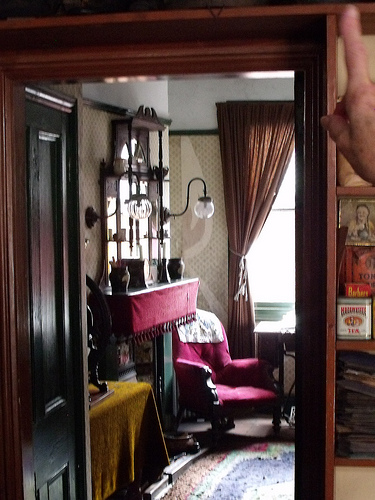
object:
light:
[161, 436, 291, 500]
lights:
[112, 149, 215, 220]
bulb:
[194, 202, 215, 220]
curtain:
[213, 99, 296, 358]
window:
[247, 115, 295, 321]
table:
[99, 277, 200, 414]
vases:
[108, 266, 130, 293]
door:
[0, 77, 87, 500]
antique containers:
[84, 102, 215, 292]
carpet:
[157, 438, 296, 500]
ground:
[130, 415, 296, 500]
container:
[336, 296, 371, 342]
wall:
[81, 76, 294, 135]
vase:
[167, 257, 185, 280]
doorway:
[1, 0, 339, 500]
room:
[0, 0, 375, 499]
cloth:
[103, 277, 201, 349]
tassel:
[192, 313, 198, 322]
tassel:
[184, 315, 187, 324]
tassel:
[167, 320, 170, 334]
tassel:
[159, 325, 164, 336]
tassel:
[133, 330, 144, 347]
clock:
[127, 258, 147, 291]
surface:
[142, 415, 295, 500]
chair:
[171, 309, 281, 451]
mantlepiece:
[104, 276, 202, 343]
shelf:
[333, 181, 375, 467]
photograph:
[337, 193, 375, 246]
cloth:
[86, 380, 170, 500]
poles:
[98, 105, 206, 296]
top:
[102, 275, 200, 297]